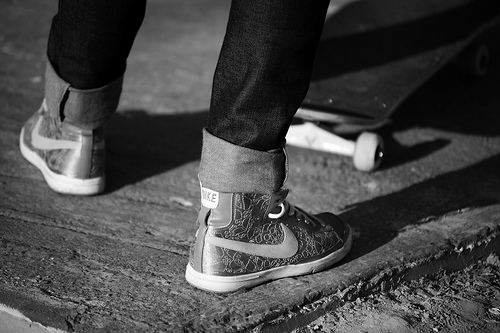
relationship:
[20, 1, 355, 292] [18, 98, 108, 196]
person wearing shoe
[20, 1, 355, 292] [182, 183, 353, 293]
person wearing shoe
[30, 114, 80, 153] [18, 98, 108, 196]
logo on shoe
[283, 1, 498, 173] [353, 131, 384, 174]
skateboard has wheel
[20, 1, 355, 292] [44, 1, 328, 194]
person wearing pants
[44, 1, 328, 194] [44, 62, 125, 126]
pants have cuff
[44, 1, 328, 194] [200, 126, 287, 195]
pants have cuff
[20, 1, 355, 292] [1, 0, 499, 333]
person standing on ground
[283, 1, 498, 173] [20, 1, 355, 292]
skateboard in front of person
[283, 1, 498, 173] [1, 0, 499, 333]
skateboard on ground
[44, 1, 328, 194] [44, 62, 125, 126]
pants has cuff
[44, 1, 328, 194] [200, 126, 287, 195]
pants has cuff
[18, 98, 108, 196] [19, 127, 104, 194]
shoe has sole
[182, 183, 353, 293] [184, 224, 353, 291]
shoe has sole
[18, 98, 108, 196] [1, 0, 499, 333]
shoe on ground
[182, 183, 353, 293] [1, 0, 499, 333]
shoe on ground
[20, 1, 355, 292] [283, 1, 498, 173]
person near skateboard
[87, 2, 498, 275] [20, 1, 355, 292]
shadow before person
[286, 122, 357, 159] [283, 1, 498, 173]
axle on skateboard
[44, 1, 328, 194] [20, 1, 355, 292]
pants on person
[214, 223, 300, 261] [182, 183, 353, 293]
logo on shoe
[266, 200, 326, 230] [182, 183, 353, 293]
laces on shoe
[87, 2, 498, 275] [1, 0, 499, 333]
shadow on ground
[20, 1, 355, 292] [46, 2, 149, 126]
person has leg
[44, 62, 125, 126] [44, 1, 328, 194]
cuff on pants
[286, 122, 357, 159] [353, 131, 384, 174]
axle attached wheel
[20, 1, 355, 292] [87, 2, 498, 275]
person has shadow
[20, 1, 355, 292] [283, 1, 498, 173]
person standing beside skateboard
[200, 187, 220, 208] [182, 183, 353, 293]
logo on shoe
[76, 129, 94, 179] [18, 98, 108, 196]
stripe on shoe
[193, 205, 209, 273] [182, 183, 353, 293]
stripe on shoe